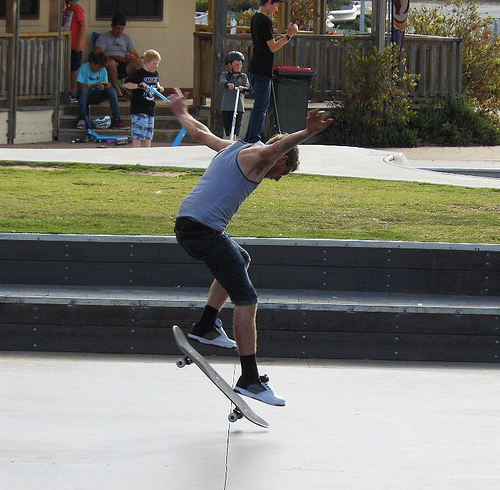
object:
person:
[164, 86, 334, 407]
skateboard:
[171, 323, 270, 429]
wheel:
[227, 412, 239, 423]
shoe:
[233, 372, 286, 407]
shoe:
[186, 317, 240, 351]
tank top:
[175, 138, 262, 234]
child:
[122, 47, 165, 148]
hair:
[142, 48, 161, 64]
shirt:
[122, 66, 160, 117]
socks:
[239, 352, 260, 383]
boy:
[218, 49, 251, 140]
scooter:
[225, 85, 246, 141]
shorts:
[130, 112, 155, 141]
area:
[0, 159, 499, 244]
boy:
[74, 49, 131, 130]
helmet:
[223, 50, 246, 65]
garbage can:
[263, 63, 318, 140]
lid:
[273, 63, 318, 74]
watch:
[283, 33, 293, 42]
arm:
[257, 18, 292, 54]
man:
[93, 13, 144, 102]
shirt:
[94, 29, 137, 63]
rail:
[225, 32, 464, 106]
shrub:
[323, 29, 422, 148]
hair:
[265, 131, 301, 173]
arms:
[256, 128, 313, 166]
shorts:
[172, 217, 261, 306]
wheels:
[175, 357, 187, 369]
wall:
[0, 230, 499, 365]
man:
[241, 0, 301, 147]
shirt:
[246, 10, 276, 78]